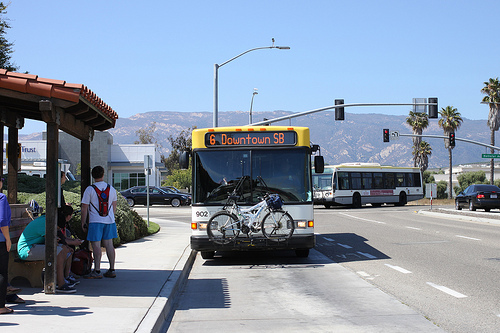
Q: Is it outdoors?
A: Yes, it is outdoors.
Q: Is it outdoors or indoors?
A: It is outdoors.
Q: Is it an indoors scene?
A: No, it is outdoors.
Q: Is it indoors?
A: No, it is outdoors.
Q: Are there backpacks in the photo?
A: Yes, there is a backpack.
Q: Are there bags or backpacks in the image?
A: Yes, there is a backpack.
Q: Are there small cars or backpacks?
A: Yes, there is a small backpack.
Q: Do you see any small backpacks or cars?
A: Yes, there is a small backpack.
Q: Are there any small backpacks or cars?
A: Yes, there is a small backpack.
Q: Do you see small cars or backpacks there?
A: Yes, there is a small backpack.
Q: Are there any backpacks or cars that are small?
A: Yes, the backpack is small.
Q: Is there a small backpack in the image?
A: Yes, there is a small backpack.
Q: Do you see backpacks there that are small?
A: Yes, there is a backpack that is small.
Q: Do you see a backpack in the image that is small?
A: Yes, there is a backpack that is small.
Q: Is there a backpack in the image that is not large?
A: Yes, there is a small backpack.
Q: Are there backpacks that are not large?
A: Yes, there is a small backpack.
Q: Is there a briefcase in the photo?
A: No, there are no briefcases.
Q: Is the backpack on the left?
A: Yes, the backpack is on the left of the image.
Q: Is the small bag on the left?
A: Yes, the backpack is on the left of the image.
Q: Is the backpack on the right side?
A: No, the backpack is on the left of the image.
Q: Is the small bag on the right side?
A: No, the backpack is on the left of the image.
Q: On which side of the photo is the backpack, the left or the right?
A: The backpack is on the left of the image.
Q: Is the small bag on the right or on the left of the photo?
A: The backpack is on the left of the image.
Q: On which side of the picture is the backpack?
A: The backpack is on the left of the image.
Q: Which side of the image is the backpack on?
A: The backpack is on the left of the image.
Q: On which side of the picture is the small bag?
A: The backpack is on the left of the image.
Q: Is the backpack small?
A: Yes, the backpack is small.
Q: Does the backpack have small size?
A: Yes, the backpack is small.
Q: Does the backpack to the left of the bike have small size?
A: Yes, the backpack is small.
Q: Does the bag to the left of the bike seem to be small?
A: Yes, the backpack is small.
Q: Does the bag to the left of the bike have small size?
A: Yes, the backpack is small.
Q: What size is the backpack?
A: The backpack is small.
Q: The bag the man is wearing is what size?
A: The backpack is small.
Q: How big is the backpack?
A: The backpack is small.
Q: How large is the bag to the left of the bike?
A: The backpack is small.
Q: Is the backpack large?
A: No, the backpack is small.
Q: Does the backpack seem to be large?
A: No, the backpack is small.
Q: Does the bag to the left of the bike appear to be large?
A: No, the backpack is small.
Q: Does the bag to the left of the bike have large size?
A: No, the backpack is small.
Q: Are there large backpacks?
A: No, there is a backpack but it is small.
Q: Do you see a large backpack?
A: No, there is a backpack but it is small.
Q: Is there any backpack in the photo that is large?
A: No, there is a backpack but it is small.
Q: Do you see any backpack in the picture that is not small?
A: No, there is a backpack but it is small.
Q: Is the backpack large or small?
A: The backpack is small.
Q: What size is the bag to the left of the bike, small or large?
A: The backpack is small.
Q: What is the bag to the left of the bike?
A: The bag is a backpack.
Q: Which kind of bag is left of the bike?
A: The bag is a backpack.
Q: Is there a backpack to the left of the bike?
A: Yes, there is a backpack to the left of the bike.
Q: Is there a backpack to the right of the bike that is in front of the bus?
A: No, the backpack is to the left of the bike.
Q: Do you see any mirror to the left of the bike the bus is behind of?
A: No, there is a backpack to the left of the bike.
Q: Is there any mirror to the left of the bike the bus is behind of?
A: No, there is a backpack to the left of the bike.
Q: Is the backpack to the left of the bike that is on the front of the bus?
A: Yes, the backpack is to the left of the bike.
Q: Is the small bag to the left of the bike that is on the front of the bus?
A: Yes, the backpack is to the left of the bike.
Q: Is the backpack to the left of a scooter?
A: No, the backpack is to the left of the bike.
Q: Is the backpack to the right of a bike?
A: No, the backpack is to the left of a bike.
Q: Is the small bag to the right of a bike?
A: No, the backpack is to the left of a bike.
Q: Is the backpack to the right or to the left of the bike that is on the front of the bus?
A: The backpack is to the left of the bike.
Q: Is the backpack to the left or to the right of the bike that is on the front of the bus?
A: The backpack is to the left of the bike.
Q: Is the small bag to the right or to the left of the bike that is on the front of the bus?
A: The backpack is to the left of the bike.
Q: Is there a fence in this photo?
A: No, there are no fences.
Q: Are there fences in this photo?
A: No, there are no fences.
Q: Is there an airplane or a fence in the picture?
A: No, there are no fences or airplanes.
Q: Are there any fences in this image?
A: No, there are no fences.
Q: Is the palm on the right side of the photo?
A: Yes, the palm is on the right of the image.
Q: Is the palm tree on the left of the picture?
A: No, the palm tree is on the right of the image.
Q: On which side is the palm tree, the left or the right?
A: The palm tree is on the right of the image.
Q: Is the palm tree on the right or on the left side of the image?
A: The palm tree is on the right of the image.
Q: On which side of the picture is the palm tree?
A: The palm tree is on the right of the image.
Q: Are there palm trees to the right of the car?
A: No, the palm tree is to the left of the car.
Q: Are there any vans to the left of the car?
A: No, there is a palm tree to the left of the car.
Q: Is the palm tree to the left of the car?
A: Yes, the palm tree is to the left of the car.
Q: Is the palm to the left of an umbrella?
A: No, the palm is to the left of the car.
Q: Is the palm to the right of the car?
A: No, the palm is to the left of the car.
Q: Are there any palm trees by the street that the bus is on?
A: Yes, there is a palm tree by the street.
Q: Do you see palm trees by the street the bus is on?
A: Yes, there is a palm tree by the street.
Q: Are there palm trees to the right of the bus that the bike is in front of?
A: Yes, there is a palm tree to the right of the bus.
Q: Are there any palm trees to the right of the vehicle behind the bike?
A: Yes, there is a palm tree to the right of the bus.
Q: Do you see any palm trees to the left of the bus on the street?
A: No, the palm tree is to the right of the bus.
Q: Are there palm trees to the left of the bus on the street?
A: No, the palm tree is to the right of the bus.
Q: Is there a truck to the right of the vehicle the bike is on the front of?
A: No, there is a palm tree to the right of the bus.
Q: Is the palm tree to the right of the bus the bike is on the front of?
A: Yes, the palm tree is to the right of the bus.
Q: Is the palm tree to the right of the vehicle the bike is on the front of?
A: Yes, the palm tree is to the right of the bus.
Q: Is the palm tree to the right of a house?
A: No, the palm tree is to the right of the bus.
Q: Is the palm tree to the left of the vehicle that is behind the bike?
A: No, the palm tree is to the right of the bus.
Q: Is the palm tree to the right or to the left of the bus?
A: The palm tree is to the right of the bus.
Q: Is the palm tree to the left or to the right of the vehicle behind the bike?
A: The palm tree is to the right of the bus.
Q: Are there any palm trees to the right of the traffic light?
A: Yes, there is a palm tree to the right of the traffic light.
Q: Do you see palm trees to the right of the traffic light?
A: Yes, there is a palm tree to the right of the traffic light.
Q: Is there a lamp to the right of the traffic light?
A: No, there is a palm tree to the right of the traffic light.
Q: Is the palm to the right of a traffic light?
A: Yes, the palm is to the right of a traffic light.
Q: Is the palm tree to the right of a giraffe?
A: No, the palm tree is to the right of a traffic light.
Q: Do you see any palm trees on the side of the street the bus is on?
A: Yes, there is a palm tree on the side of the street.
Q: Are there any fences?
A: No, there are no fences.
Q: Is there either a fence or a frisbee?
A: No, there are no fences or frisbees.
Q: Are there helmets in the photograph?
A: No, there are no helmets.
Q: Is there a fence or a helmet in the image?
A: No, there are no helmets or fences.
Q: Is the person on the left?
A: Yes, the person is on the left of the image.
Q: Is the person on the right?
A: No, the person is on the left of the image.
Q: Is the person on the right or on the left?
A: The person is on the left of the image.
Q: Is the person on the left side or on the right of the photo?
A: The person is on the left of the image.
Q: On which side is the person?
A: The person is on the left of the image.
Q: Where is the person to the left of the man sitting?
A: The person is sitting at the bus stop.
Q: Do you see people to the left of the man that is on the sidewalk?
A: Yes, there is a person to the left of the man.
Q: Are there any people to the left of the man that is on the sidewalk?
A: Yes, there is a person to the left of the man.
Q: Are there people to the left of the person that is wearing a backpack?
A: Yes, there is a person to the left of the man.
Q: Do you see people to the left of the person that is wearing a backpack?
A: Yes, there is a person to the left of the man.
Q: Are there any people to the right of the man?
A: No, the person is to the left of the man.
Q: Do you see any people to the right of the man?
A: No, the person is to the left of the man.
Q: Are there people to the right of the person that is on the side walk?
A: No, the person is to the left of the man.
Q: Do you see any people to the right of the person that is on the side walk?
A: No, the person is to the left of the man.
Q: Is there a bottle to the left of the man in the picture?
A: No, there is a person to the left of the man.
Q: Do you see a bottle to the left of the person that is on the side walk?
A: No, there is a person to the left of the man.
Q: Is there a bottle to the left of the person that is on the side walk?
A: No, there is a person to the left of the man.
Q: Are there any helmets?
A: No, there are no helmets.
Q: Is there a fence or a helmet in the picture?
A: No, there are no helmets or fences.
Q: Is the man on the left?
A: Yes, the man is on the left of the image.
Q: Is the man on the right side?
A: No, the man is on the left of the image.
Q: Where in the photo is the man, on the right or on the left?
A: The man is on the left of the image.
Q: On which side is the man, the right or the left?
A: The man is on the left of the image.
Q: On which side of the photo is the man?
A: The man is on the left of the image.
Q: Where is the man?
A: The man is on the sidewalk.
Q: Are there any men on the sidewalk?
A: Yes, there is a man on the sidewalk.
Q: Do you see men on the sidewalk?
A: Yes, there is a man on the sidewalk.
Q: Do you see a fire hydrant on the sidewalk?
A: No, there is a man on the sidewalk.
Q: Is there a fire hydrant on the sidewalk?
A: No, there is a man on the sidewalk.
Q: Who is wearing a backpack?
A: The man is wearing a backpack.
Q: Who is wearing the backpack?
A: The man is wearing a backpack.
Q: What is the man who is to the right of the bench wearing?
A: The man is wearing a backpack.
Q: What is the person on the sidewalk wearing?
A: The man is wearing a backpack.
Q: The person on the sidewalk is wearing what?
A: The man is wearing a backpack.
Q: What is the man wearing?
A: The man is wearing a backpack.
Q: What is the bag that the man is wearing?
A: The bag is a backpack.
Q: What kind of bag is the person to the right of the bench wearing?
A: The man is wearing a backpack.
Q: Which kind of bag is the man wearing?
A: The man is wearing a backpack.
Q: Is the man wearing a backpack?
A: Yes, the man is wearing a backpack.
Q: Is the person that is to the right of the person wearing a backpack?
A: Yes, the man is wearing a backpack.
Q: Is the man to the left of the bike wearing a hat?
A: No, the man is wearing a backpack.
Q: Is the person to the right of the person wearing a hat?
A: No, the man is wearing a backpack.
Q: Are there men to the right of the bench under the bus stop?
A: Yes, there is a man to the right of the bench.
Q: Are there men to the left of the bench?
A: No, the man is to the right of the bench.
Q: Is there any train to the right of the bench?
A: No, there is a man to the right of the bench.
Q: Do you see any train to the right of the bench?
A: No, there is a man to the right of the bench.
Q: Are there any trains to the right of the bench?
A: No, there is a man to the right of the bench.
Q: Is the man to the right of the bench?
A: Yes, the man is to the right of the bench.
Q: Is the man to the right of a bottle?
A: No, the man is to the right of the bench.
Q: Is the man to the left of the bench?
A: No, the man is to the right of the bench.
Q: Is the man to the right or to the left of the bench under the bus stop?
A: The man is to the right of the bench.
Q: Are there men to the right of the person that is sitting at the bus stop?
A: Yes, there is a man to the right of the person.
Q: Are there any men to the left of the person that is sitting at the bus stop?
A: No, the man is to the right of the person.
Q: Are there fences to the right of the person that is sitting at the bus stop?
A: No, there is a man to the right of the person.